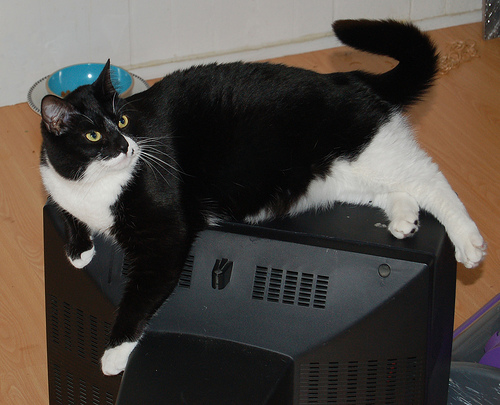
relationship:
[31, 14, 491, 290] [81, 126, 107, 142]
cat has eye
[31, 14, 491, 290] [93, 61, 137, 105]
cat has ear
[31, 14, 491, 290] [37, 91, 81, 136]
cat has ear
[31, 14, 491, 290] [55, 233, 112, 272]
cat has paw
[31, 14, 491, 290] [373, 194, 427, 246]
cat has paw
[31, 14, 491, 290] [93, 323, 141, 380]
cat has paw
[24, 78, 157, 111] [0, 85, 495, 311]
plate on floor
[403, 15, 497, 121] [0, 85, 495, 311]
section of floor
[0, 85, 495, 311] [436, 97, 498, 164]
floor made of wood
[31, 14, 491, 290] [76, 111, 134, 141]
cat has eyes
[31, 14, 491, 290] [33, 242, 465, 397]
cat on television set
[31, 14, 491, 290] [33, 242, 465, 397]
cat on television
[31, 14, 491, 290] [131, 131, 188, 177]
cat has whiskers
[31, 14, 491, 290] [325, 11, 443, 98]
cat has tail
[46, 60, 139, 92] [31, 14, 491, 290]
bowl behind cat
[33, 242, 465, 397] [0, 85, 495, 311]
television set on floor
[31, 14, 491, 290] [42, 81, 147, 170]
cat has head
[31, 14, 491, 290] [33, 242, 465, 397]
cat on top of television set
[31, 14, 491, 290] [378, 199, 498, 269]
cat has paws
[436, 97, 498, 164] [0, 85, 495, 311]
part of floor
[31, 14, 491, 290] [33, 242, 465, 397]
cat on tv set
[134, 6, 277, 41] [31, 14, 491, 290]
wall behind cat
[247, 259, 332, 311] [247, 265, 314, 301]
vents for cooling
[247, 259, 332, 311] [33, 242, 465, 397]
vents on tv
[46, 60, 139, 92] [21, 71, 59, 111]
bowl on saucer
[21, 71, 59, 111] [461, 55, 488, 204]
saucer on table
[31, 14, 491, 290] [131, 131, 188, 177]
cat has wiskers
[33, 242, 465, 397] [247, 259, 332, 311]
television has vents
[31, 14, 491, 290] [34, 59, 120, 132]
cat has ears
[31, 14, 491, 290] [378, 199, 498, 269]
cat has back paws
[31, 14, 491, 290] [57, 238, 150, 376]
cat has front paws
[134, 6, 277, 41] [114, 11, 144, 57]
wall has crack